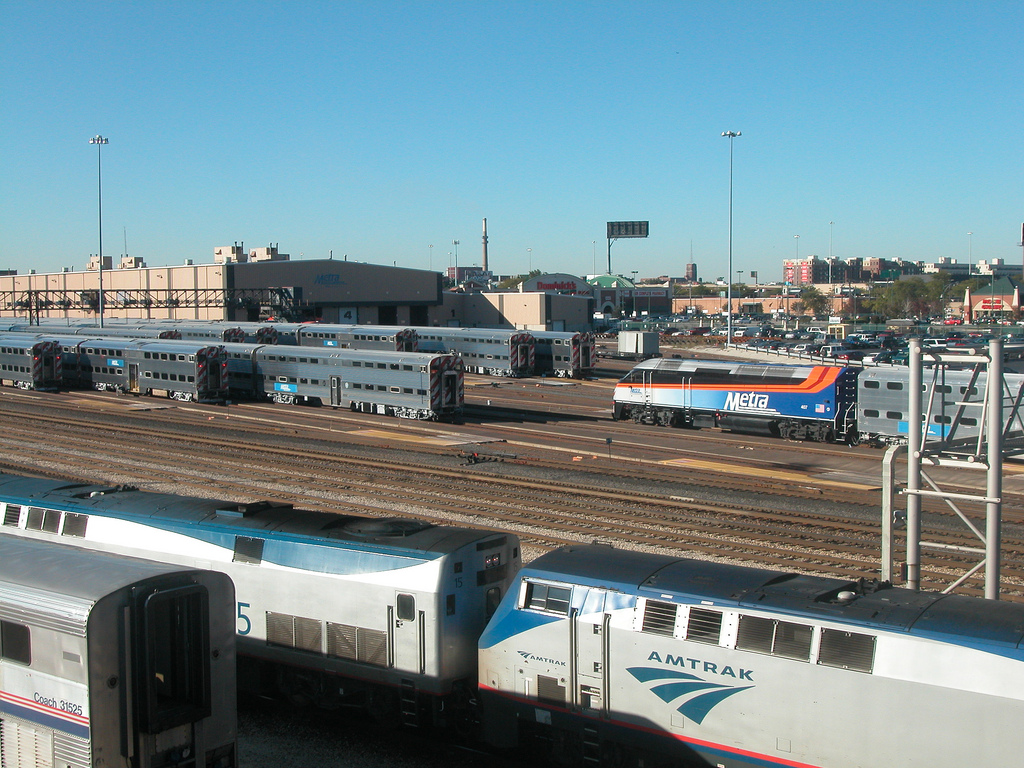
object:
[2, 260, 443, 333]
building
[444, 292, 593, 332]
building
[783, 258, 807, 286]
building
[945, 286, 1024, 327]
building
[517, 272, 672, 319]
building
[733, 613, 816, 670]
window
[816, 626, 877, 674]
window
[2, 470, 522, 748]
train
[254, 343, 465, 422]
train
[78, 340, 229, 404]
train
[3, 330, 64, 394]
train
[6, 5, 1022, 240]
sky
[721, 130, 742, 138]
light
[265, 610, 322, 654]
window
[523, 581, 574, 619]
window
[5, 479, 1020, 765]
train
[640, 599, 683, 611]
vents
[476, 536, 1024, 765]
train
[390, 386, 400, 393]
windows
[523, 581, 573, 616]
glass window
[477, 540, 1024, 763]
train engine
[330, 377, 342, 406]
door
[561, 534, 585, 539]
gravel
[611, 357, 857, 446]
engine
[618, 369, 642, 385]
window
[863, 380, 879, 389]
window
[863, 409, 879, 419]
window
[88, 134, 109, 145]
lights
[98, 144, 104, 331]
pole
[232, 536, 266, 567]
glass window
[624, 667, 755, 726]
logo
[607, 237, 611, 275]
pole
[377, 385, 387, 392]
window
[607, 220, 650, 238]
sign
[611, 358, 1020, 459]
train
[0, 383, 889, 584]
tracks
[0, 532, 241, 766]
train engine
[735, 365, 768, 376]
window